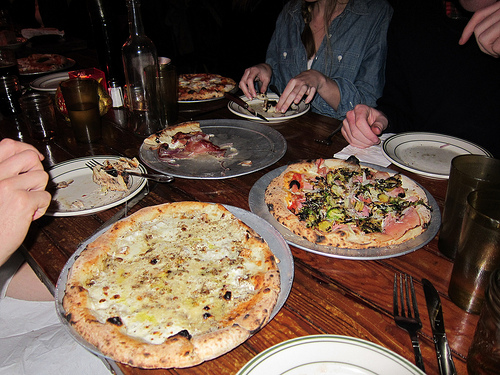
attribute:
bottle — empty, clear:
[117, 2, 165, 123]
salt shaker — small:
[105, 78, 128, 110]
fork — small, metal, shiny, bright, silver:
[84, 154, 174, 185]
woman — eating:
[233, 2, 389, 121]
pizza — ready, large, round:
[49, 197, 275, 370]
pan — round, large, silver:
[137, 115, 290, 183]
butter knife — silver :
[421, 276, 456, 373]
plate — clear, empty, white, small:
[38, 152, 148, 217]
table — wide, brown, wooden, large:
[4, 35, 496, 370]